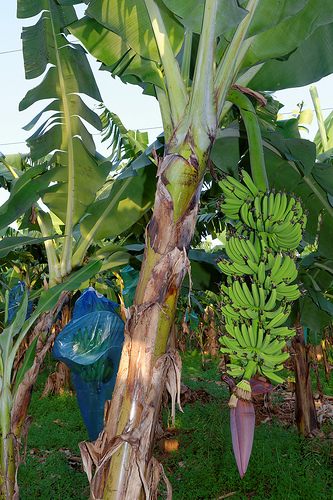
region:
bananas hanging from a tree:
[123, 52, 328, 436]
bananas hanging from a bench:
[194, 79, 323, 383]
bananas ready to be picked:
[157, 118, 319, 384]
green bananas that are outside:
[207, 118, 326, 412]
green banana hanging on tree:
[182, 107, 326, 438]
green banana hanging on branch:
[204, 159, 311, 442]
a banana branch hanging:
[142, 40, 311, 470]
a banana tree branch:
[82, 32, 314, 491]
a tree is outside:
[84, 46, 310, 476]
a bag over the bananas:
[51, 242, 219, 460]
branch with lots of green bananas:
[210, 133, 315, 479]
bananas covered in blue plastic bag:
[62, 281, 141, 440]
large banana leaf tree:
[37, 152, 111, 291]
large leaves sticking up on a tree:
[98, 2, 290, 163]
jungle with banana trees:
[5, 73, 317, 354]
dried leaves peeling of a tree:
[123, 326, 188, 497]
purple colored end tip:
[216, 325, 270, 489]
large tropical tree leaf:
[16, 27, 111, 239]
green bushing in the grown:
[181, 399, 235, 481]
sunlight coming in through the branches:
[66, 18, 175, 234]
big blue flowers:
[60, 285, 135, 443]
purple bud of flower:
[226, 383, 255, 475]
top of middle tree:
[110, 44, 276, 146]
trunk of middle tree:
[89, 117, 195, 498]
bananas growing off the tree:
[216, 171, 299, 381]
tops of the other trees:
[0, 113, 322, 303]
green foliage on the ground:
[19, 385, 331, 499]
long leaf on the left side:
[17, 3, 106, 229]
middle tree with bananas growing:
[79, 2, 292, 499]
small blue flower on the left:
[1, 278, 34, 326]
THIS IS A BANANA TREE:
[53, 2, 332, 499]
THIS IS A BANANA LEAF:
[15, 0, 112, 273]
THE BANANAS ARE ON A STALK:
[214, 86, 311, 401]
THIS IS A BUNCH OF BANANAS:
[213, 163, 310, 400]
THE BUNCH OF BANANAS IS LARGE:
[205, 165, 305, 399]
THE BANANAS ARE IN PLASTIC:
[50, 284, 130, 446]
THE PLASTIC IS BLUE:
[50, 283, 128, 446]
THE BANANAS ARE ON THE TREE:
[210, 164, 309, 391]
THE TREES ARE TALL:
[0, 0, 332, 499]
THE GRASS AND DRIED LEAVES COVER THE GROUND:
[0, 335, 332, 499]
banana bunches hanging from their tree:
[225, 242, 303, 422]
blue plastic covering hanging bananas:
[69, 289, 126, 449]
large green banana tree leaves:
[19, 20, 114, 276]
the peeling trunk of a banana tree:
[155, 125, 197, 314]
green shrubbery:
[192, 410, 265, 495]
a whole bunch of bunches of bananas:
[217, 173, 297, 384]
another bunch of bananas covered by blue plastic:
[6, 276, 36, 343]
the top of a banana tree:
[97, 7, 315, 142]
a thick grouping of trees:
[173, 291, 228, 385]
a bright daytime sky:
[10, 16, 183, 143]